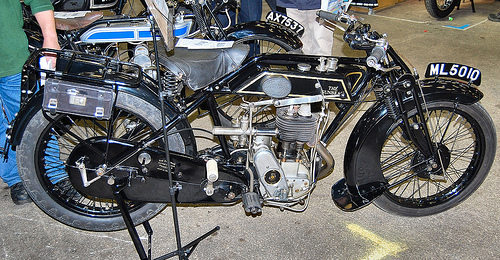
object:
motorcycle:
[21, 13, 496, 257]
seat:
[153, 43, 240, 93]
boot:
[49, 178, 84, 200]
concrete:
[8, 13, 495, 258]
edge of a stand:
[145, 100, 218, 250]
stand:
[165, 172, 205, 257]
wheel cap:
[424, 143, 454, 172]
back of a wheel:
[357, 86, 499, 218]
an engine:
[65, 127, 152, 204]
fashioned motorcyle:
[14, 10, 500, 260]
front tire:
[345, 67, 495, 218]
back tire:
[9, 86, 193, 231]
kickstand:
[94, 172, 151, 260]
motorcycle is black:
[13, 39, 499, 260]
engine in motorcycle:
[238, 101, 333, 211]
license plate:
[423, 61, 484, 85]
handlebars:
[353, 29, 405, 73]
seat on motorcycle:
[79, 16, 197, 47]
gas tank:
[255, 64, 291, 101]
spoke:
[449, 121, 475, 154]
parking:
[0, 0, 499, 260]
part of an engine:
[258, 90, 325, 161]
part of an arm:
[33, 8, 75, 73]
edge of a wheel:
[420, 73, 487, 122]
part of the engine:
[214, 95, 284, 153]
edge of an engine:
[2, 110, 48, 164]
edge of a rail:
[102, 116, 165, 153]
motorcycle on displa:
[0, 11, 499, 260]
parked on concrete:
[0, 0, 499, 260]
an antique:
[7, 13, 499, 260]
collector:
[0, 0, 87, 205]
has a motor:
[243, 136, 328, 207]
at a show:
[0, 0, 499, 260]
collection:
[13, 11, 497, 260]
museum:
[0, 0, 493, 260]